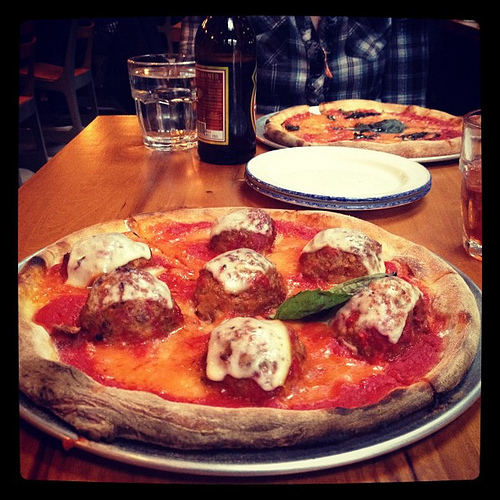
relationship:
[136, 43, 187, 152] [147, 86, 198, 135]
glass has water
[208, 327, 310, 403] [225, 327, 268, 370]
meatball has cheese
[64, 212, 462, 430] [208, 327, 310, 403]
pizza has meatball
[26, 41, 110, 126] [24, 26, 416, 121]
chairs in background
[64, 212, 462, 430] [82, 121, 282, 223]
pizza on table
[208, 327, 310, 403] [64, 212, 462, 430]
meatball on pizza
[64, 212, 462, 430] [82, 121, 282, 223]
pizza of table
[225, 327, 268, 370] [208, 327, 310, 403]
cheese of meatball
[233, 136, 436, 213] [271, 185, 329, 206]
plates has edges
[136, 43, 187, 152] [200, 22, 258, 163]
glass b bottle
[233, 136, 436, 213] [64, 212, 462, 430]
plates b pizza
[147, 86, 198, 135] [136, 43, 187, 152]
water i glass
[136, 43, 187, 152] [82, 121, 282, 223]
glass on table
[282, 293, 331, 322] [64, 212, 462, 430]
leaf on pizza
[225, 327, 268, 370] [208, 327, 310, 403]
cheese on meatball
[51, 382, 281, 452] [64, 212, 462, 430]
crust on pizza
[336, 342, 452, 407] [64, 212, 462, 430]
tomato sauce on pizza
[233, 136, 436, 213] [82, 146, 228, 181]
plates in middle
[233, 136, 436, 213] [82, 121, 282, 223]
plates on table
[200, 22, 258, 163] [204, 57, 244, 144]
bottle has beer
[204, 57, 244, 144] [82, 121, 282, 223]
beer on table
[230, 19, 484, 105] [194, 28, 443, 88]
person wearing shirt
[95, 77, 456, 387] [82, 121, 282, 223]
pizzas on table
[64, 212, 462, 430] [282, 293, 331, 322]
pizza has leaf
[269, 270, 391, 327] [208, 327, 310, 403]
leaf by meatball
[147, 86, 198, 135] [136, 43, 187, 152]
water in glass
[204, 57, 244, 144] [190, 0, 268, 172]
beer in bottle